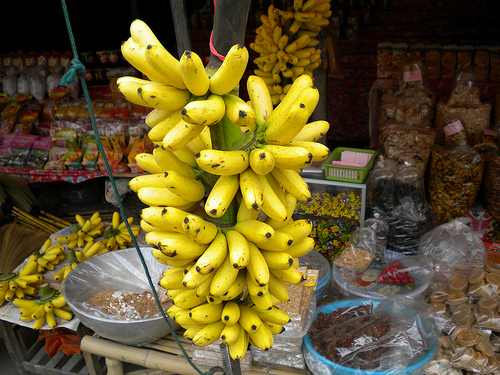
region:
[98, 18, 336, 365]
a bunch of bananas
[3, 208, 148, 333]
bananas on a platform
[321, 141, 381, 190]
a small mailbox plastic holder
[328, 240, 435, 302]
plastic food wrappings on bowl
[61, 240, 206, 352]
spices inside a bowl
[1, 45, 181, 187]
a stand full of snacks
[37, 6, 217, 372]
a green rope dragging down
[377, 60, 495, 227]
couple bags of banana peels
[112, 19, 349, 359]
bunch of bananas hanged on a stick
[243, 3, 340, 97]
bananas hanged on a stick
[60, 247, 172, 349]
a round silver bowl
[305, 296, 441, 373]
a round blue bowl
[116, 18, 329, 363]
a bunch of hanging bananas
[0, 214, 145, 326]
bananas laying on a table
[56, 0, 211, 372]
a hanging green rope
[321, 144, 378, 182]
a green rectangular basket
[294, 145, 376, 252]
a green basket sitting on a shelf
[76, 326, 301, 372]
a wooden table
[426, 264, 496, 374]
bags of cookies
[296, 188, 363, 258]
shelves of yellow flowers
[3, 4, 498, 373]
Exterior view, season, uncertain.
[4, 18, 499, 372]
Daytime view of wares, displayed at marketing venue.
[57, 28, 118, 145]
Blue cording, probably assisting in keeping covering aloft.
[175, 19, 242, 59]
Vertical strut, or pole, with red rope.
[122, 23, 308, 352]
Display of bunches of bananas.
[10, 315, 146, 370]
Crate and wooden table.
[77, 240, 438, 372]
Silver and blue bowls with edible items, encased with plastic.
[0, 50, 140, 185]
Rows of produce, arranged in bins on red fabric.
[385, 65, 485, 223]
Bags full of dried food items.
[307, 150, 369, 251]
Green, plastic box with pink papers, atop cart with produce.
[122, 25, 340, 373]
A yellow ripe banana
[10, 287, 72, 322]
A yellow ripe banana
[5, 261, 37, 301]
A yellow ripe banana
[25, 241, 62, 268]
A yellow ripe banana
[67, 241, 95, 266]
A yellow ripe banana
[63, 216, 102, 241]
A yellow ripe banana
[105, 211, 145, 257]
A yellow ripe banana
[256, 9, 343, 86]
A yellow ripe banana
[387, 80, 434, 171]
A parket of cereals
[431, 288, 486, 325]
A parket of cereals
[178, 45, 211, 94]
a ripe yellow banana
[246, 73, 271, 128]
a ripe yellow banana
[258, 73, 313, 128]
a ripe yellow banana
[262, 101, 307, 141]
a ripe yellow banana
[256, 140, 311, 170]
a ripe yellow banana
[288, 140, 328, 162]
a ripe yellow banana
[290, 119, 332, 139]
a ripe yellow banana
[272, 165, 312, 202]
a ripe yellow banana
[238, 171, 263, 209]
a ripe yellow banana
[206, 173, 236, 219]
a ripe yellow banana